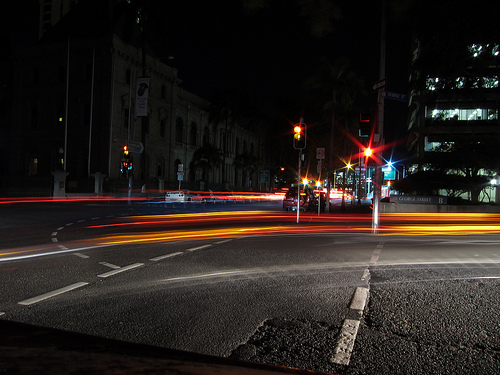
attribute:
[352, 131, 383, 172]
light — red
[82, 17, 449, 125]
sky — dark, black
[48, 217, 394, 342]
lines — white, dotted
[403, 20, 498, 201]
building — office building, multi story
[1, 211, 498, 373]
road — marked, tarmac road, tarmac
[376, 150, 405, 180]
burst — blue, shiny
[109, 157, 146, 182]
signal — red and green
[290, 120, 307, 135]
street light — bright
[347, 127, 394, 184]
star — shiny, red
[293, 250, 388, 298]
road — tarmac road, marked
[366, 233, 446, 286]
road — marked, tarmac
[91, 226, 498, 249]
light — yellow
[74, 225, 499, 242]
light — yellow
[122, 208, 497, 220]
light — yellow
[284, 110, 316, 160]
street light — bright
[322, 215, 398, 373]
line — white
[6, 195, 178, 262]
line — white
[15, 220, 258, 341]
line — white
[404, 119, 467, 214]
tree — on the right side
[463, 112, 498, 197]
tree — on the right side